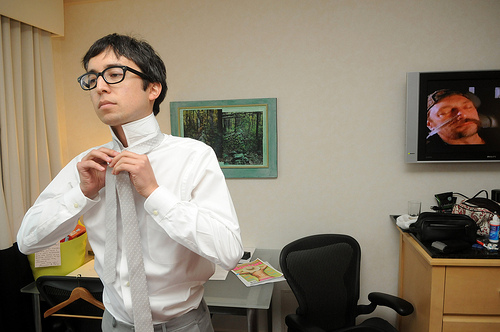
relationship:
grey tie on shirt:
[96, 126, 161, 330] [19, 134, 249, 302]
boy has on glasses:
[10, 31, 242, 329] [75, 66, 151, 87]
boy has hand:
[10, 31, 242, 329] [91, 143, 160, 202]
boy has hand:
[10, 31, 241, 330] [79, 148, 162, 200]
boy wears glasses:
[10, 31, 242, 329] [67, 63, 172, 105]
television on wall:
[402, 70, 499, 162] [53, 1, 498, 325]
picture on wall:
[164, 93, 284, 183] [158, 6, 410, 231]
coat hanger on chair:
[40, 272, 106, 323] [39, 271, 101, 329]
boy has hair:
[10, 31, 242, 329] [76, 33, 170, 80]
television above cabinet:
[402, 70, 499, 162] [397, 202, 498, 328]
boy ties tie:
[10, 31, 242, 329] [101, 131, 168, 328]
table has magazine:
[203, 246, 280, 331] [220, 255, 290, 293]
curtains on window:
[0, 16, 63, 253] [1, 4, 66, 275]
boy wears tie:
[10, 31, 242, 329] [102, 128, 157, 328]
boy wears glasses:
[10, 31, 242, 329] [77, 62, 161, 86]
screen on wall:
[405, 67, 499, 162] [53, 1, 498, 325]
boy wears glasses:
[10, 31, 242, 329] [69, 49, 171, 97]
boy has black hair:
[10, 31, 242, 329] [79, 35, 168, 114]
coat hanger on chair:
[39, 272, 106, 322] [33, 270, 105, 330]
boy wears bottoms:
[10, 31, 242, 329] [103, 290, 208, 330]